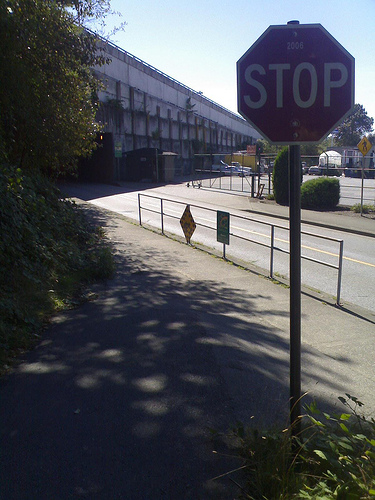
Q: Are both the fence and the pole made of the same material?
A: Yes, both the fence and the pole are made of metal.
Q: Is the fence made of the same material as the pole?
A: Yes, both the fence and the pole are made of metal.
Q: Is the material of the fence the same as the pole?
A: Yes, both the fence and the pole are made of metal.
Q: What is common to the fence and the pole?
A: The material, both the fence and the pole are metallic.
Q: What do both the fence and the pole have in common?
A: The material, both the fence and the pole are metallic.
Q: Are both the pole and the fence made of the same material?
A: Yes, both the pole and the fence are made of metal.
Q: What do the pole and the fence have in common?
A: The material, both the pole and the fence are metallic.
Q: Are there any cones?
A: No, there are no cones.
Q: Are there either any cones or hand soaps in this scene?
A: No, there are no cones or hand soaps.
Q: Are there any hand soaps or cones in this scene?
A: No, there are no cones or hand soaps.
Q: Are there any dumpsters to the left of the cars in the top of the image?
A: Yes, there is a dumpster to the left of the cars.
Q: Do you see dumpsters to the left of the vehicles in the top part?
A: Yes, there is a dumpster to the left of the cars.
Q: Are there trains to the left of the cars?
A: No, there is a dumpster to the left of the cars.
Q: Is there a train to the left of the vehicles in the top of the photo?
A: No, there is a dumpster to the left of the cars.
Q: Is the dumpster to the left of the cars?
A: Yes, the dumpster is to the left of the cars.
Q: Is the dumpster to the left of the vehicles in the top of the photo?
A: Yes, the dumpster is to the left of the cars.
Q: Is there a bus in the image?
A: No, there are no buses.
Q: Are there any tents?
A: No, there are no tents.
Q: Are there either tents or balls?
A: No, there are no tents or balls.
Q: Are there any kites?
A: No, there are no kites.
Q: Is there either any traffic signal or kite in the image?
A: No, there are no kites or traffic lights.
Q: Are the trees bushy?
A: Yes, the trees are bushy.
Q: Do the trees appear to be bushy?
A: Yes, the trees are bushy.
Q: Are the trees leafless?
A: No, the trees are bushy.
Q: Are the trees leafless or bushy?
A: The trees are bushy.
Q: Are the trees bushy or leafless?
A: The trees are bushy.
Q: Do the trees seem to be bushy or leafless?
A: The trees are bushy.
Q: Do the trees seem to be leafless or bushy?
A: The trees are bushy.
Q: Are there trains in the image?
A: No, there are no trains.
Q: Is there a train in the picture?
A: No, there are no trains.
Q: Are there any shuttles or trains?
A: No, there are no trains or shuttles.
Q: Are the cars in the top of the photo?
A: Yes, the cars are in the top of the image.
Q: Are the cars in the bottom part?
A: No, the cars are in the top of the image.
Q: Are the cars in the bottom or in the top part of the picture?
A: The cars are in the top of the image.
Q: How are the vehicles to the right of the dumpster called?
A: The vehicles are cars.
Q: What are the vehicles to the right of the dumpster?
A: The vehicles are cars.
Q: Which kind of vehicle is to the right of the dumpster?
A: The vehicles are cars.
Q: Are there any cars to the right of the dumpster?
A: Yes, there are cars to the right of the dumpster.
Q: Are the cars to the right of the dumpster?
A: Yes, the cars are to the right of the dumpster.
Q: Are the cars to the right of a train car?
A: No, the cars are to the right of the dumpster.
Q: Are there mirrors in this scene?
A: No, there are no mirrors.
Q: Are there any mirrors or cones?
A: No, there are no mirrors or cones.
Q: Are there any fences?
A: Yes, there is a fence.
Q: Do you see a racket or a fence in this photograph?
A: Yes, there is a fence.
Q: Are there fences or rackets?
A: Yes, there is a fence.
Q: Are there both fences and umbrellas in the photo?
A: No, there is a fence but no umbrellas.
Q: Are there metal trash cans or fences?
A: Yes, there is a metal fence.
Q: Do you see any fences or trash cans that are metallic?
A: Yes, the fence is metallic.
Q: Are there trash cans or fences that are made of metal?
A: Yes, the fence is made of metal.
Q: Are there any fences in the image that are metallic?
A: Yes, there is a metal fence.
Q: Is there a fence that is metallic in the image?
A: Yes, there is a metal fence.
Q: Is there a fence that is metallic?
A: Yes, there is a fence that is metallic.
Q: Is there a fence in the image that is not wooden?
A: Yes, there is a metallic fence.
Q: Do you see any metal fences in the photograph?
A: Yes, there is a fence that is made of metal.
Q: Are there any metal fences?
A: Yes, there is a fence that is made of metal.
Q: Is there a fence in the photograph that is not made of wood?
A: Yes, there is a fence that is made of metal.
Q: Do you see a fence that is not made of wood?
A: Yes, there is a fence that is made of metal.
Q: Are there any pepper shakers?
A: No, there are no pepper shakers.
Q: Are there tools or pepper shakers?
A: No, there are no pepper shakers or tools.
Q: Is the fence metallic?
A: Yes, the fence is metallic.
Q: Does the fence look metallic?
A: Yes, the fence is metallic.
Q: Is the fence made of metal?
A: Yes, the fence is made of metal.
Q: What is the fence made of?
A: The fence is made of metal.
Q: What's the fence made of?
A: The fence is made of metal.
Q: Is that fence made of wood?
A: No, the fence is made of metal.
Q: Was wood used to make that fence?
A: No, the fence is made of metal.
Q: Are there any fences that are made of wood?
A: No, there is a fence but it is made of metal.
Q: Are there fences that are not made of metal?
A: No, there is a fence but it is made of metal.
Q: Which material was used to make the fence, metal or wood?
A: The fence is made of metal.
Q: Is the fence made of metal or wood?
A: The fence is made of metal.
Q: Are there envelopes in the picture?
A: No, there are no envelopes.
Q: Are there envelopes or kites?
A: No, there are no envelopes or kites.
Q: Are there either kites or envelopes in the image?
A: No, there are no envelopes or kites.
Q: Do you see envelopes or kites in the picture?
A: No, there are no envelopes or kites.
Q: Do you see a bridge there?
A: Yes, there is a bridge.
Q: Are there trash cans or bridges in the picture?
A: Yes, there is a bridge.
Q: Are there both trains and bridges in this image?
A: No, there is a bridge but no trains.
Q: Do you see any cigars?
A: No, there are no cigars.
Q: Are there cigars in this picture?
A: No, there are no cigars.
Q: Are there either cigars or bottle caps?
A: No, there are no cigars or bottle caps.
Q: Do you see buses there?
A: No, there are no buses.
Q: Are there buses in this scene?
A: No, there are no buses.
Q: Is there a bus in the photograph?
A: No, there are no buses.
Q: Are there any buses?
A: No, there are no buses.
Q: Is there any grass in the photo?
A: Yes, there is grass.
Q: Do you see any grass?
A: Yes, there is grass.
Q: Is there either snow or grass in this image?
A: Yes, there is grass.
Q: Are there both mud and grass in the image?
A: No, there is grass but no mud.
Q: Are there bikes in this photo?
A: No, there are no bikes.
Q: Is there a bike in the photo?
A: No, there are no bikes.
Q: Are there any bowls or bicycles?
A: No, there are no bicycles or bowls.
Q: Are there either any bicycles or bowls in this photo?
A: No, there are no bicycles or bowls.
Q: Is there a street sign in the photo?
A: Yes, there is a street sign.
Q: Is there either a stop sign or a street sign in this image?
A: Yes, there is a street sign.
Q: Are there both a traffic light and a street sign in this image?
A: No, there is a street sign but no traffic lights.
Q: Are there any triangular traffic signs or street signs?
A: Yes, there is a triangular street sign.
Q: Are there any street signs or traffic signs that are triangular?
A: Yes, the street sign is triangular.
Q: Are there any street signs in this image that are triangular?
A: Yes, there is a triangular street sign.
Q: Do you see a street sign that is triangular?
A: Yes, there is a street sign that is triangular.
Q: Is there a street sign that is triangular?
A: Yes, there is a street sign that is triangular.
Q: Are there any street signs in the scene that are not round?
A: Yes, there is a triangular street sign.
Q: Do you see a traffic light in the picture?
A: No, there are no traffic lights.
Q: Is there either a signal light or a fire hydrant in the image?
A: No, there are no traffic lights or fire hydrants.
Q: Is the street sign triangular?
A: Yes, the street sign is triangular.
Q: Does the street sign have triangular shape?
A: Yes, the street sign is triangular.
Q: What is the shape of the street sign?
A: The street sign is triangular.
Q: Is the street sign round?
A: No, the street sign is triangular.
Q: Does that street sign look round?
A: No, the street sign is triangular.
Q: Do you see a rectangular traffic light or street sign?
A: No, there is a street sign but it is triangular.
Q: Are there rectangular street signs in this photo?
A: No, there is a street sign but it is triangular.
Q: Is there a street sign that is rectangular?
A: No, there is a street sign but it is triangular.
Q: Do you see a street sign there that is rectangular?
A: No, there is a street sign but it is triangular.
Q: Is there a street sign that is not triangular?
A: No, there is a street sign but it is triangular.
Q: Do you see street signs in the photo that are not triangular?
A: No, there is a street sign but it is triangular.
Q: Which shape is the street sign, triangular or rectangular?
A: The street sign is triangular.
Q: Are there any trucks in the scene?
A: No, there are no trucks.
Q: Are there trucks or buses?
A: No, there are no trucks or buses.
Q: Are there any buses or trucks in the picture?
A: No, there are no trucks or buses.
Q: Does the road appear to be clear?
A: Yes, the road is clear.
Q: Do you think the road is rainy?
A: No, the road is clear.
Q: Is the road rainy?
A: No, the road is clear.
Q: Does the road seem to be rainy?
A: No, the road is clear.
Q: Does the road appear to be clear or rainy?
A: The road is clear.